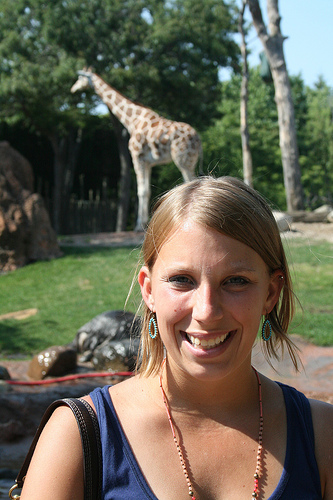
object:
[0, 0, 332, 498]
zoo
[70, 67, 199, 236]
giraffe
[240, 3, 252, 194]
trees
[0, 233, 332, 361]
grass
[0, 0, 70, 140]
trees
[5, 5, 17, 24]
leaves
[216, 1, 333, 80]
sky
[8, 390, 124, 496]
purse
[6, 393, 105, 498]
strap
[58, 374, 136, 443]
shoulder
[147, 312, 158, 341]
earrings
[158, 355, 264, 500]
necklace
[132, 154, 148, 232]
legs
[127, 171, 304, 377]
hair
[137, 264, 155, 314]
ear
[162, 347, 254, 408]
neck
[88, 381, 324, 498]
tanktop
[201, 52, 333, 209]
tree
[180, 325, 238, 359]
smile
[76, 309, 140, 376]
rocks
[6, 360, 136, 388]
hose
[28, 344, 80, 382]
rock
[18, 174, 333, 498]
girl